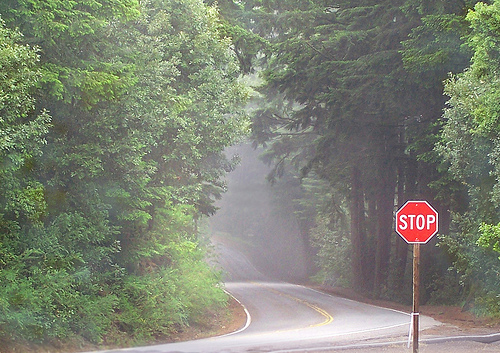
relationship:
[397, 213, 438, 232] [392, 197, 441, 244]
letters on sign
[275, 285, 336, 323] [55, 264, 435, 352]
stripe on road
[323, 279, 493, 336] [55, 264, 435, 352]
dirt side road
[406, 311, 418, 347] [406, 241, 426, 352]
ribbon on pole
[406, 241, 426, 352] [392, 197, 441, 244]
pole holding sign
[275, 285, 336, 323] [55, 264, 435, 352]
stripe in road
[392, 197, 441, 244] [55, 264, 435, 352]
sign in road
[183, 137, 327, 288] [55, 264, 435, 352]
foggy on road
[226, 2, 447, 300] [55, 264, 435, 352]
tree on road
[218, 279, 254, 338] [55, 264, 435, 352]
line in road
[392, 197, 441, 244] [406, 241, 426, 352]
sign on pole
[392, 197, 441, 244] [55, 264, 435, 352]
sign on road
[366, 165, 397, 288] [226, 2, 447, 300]
trunk of tree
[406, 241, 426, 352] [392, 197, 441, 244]
pole under sign